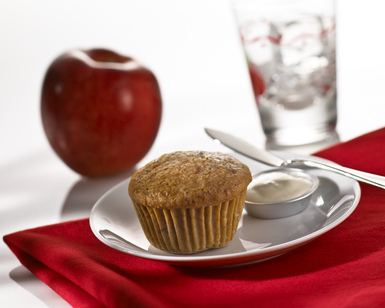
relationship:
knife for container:
[204, 126, 384, 188] [243, 165, 321, 219]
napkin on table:
[4, 127, 383, 307] [1, 54, 384, 305]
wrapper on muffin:
[129, 188, 249, 253] [127, 152, 253, 254]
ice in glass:
[243, 19, 281, 68] [234, 1, 340, 149]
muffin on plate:
[127, 152, 253, 254] [89, 149, 361, 268]